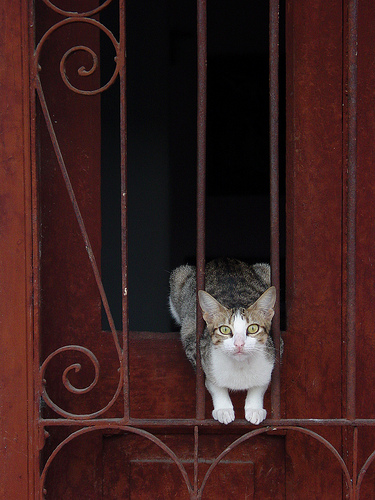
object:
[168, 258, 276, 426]
cat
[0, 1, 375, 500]
door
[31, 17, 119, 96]
form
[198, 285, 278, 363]
head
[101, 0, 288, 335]
interior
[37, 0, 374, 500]
wood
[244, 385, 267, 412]
legs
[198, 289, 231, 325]
ears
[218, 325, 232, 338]
eyes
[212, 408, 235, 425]
paws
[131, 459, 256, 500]
panel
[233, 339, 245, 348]
nose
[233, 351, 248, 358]
mouth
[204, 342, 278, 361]
whiskers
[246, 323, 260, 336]
left eye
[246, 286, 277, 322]
left ear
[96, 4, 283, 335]
window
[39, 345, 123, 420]
swirl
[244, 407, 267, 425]
left paw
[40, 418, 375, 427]
rail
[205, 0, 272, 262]
opening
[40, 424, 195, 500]
object